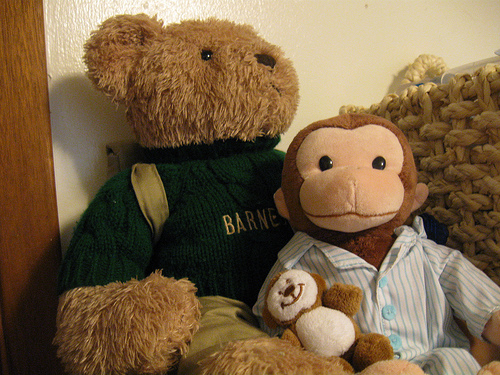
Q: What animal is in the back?
A: A bear.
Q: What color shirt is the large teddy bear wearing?
A: Green.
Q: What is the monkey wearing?
A: Striped pajamas.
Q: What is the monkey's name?
A: Curious George.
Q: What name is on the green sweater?
A: Barney.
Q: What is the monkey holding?
A: A Bear.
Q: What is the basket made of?
A: Wicker.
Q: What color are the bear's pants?
A: Khaki.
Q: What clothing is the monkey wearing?
A: Pajamas.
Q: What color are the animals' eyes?
A: Black.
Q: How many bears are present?
A: Two.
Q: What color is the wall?
A: White.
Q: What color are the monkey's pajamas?
A: Blue.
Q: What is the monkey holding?
A: Teddy Bear.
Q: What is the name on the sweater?
A: BARNEY.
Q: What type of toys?
A: Stuffed Animals.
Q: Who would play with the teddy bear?
A: Children.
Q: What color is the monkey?
A: Brown and Tan.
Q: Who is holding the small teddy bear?
A: Monkey.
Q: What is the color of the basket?
A: Tan.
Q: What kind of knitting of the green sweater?
A: Cable.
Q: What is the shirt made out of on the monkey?
A: Cotton.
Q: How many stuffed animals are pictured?
A: Three.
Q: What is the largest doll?
A: A teddy bear.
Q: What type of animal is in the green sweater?
A: Bear.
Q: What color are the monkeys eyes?
A: Black.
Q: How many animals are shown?
A: Three.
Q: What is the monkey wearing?
A: Pajamas.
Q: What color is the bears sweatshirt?
A: Green.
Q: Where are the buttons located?
A: Monkeys pajamas.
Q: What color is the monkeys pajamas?
A: White.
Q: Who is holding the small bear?
A: Monkey.